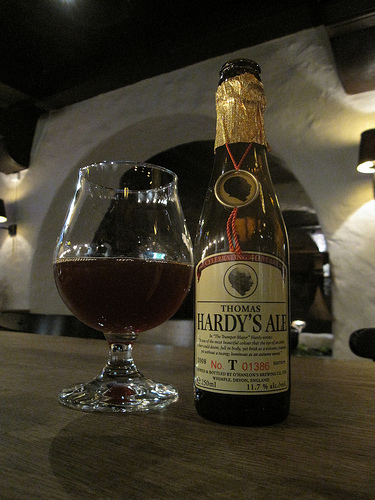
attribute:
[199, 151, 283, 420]
bottle — brown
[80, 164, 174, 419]
glass — clear, wine, full, bumpy, liquor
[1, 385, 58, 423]
table — brown, wooden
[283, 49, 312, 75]
wall — white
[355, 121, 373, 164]
lamp — black, brown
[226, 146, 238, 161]
string — red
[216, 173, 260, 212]
medallion — gold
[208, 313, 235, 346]
text — black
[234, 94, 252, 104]
foil — gold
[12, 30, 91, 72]
ceiling — black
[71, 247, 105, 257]
bubbles — line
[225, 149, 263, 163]
liqour — brown